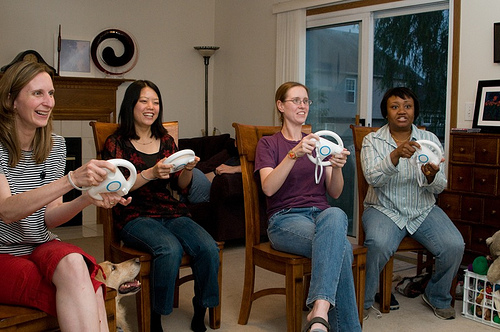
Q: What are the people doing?
A: Playing a game.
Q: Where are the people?
A: Living room.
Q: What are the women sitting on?
A: Table chairs.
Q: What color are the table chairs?
A: Brown.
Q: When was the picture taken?
A: During the day.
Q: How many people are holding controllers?
A: 4.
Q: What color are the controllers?
A: White and blue.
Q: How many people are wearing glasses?
A: 1.